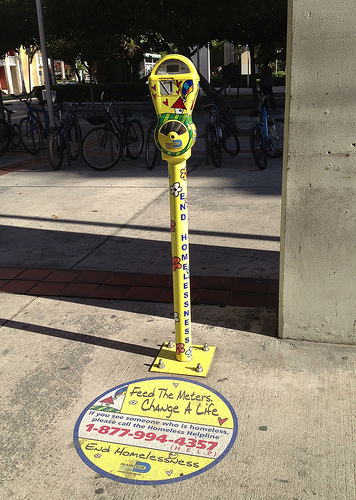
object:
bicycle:
[250, 89, 278, 171]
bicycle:
[201, 92, 240, 168]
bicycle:
[81, 91, 144, 170]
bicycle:
[47, 99, 81, 166]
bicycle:
[12, 90, 60, 155]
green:
[155, 112, 193, 155]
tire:
[49, 127, 64, 170]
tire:
[19, 117, 41, 155]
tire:
[222, 121, 241, 155]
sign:
[72, 376, 237, 485]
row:
[1, 96, 278, 170]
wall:
[278, 0, 355, 346]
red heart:
[218, 417, 228, 426]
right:
[218, 415, 228, 426]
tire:
[250, 126, 267, 170]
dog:
[278, 363, 341, 457]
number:
[86, 424, 218, 451]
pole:
[167, 162, 192, 361]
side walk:
[1, 116, 354, 498]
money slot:
[160, 78, 174, 95]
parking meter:
[148, 53, 216, 378]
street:
[1, 293, 353, 498]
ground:
[0, 236, 355, 495]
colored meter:
[148, 53, 200, 162]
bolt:
[195, 363, 203, 373]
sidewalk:
[0, 108, 353, 497]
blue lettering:
[180, 192, 190, 344]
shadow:
[32, 191, 117, 291]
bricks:
[0, 265, 278, 307]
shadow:
[0, 313, 157, 357]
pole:
[276, 2, 345, 342]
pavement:
[2, 166, 345, 498]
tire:
[81, 127, 122, 171]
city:
[1, 1, 354, 496]